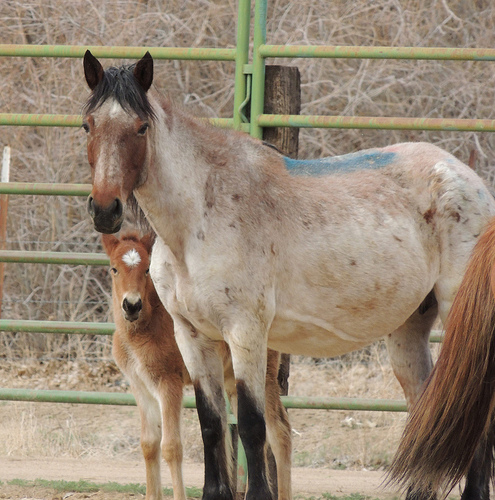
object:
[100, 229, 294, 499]
horse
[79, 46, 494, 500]
horse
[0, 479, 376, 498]
grass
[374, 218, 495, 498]
tail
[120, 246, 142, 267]
spot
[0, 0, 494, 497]
fence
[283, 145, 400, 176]
mark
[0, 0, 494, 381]
grass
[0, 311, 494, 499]
field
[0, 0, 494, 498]
pen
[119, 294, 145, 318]
nose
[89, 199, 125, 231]
nose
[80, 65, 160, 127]
hair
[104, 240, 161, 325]
face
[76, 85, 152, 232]
face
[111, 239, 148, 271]
horse's forehead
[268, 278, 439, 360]
stomach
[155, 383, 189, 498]
legs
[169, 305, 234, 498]
legs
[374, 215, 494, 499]
animal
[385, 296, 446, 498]
legs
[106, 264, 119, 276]
eye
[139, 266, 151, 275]
eye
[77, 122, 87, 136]
eye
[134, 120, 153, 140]
eye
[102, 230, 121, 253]
ear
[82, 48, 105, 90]
ear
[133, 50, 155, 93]
ear